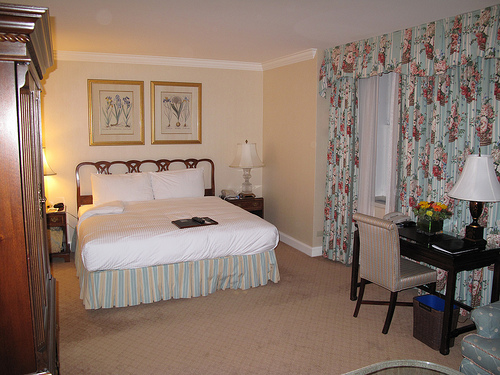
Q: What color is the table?
A: Black.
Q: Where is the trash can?
A: Under the table.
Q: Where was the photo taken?
A: In a bedroom.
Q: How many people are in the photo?
A: None.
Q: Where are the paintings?
A: On the wall.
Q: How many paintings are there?
A: Two.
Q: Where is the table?
A: On the right.